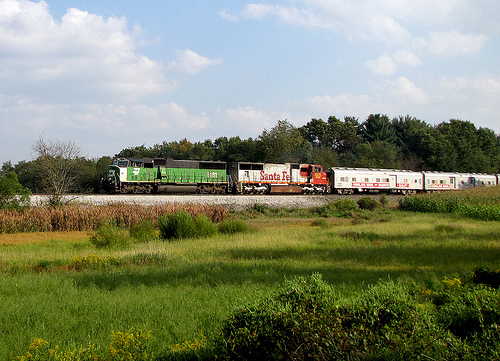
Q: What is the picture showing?
A: It is showing a field.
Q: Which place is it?
A: It is a field.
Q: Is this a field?
A: Yes, it is a field.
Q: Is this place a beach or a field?
A: It is a field.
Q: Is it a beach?
A: No, it is a field.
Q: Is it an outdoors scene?
A: Yes, it is outdoors.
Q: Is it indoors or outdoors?
A: It is outdoors.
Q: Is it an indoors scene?
A: No, it is outdoors.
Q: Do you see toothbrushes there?
A: No, there are no toothbrushes.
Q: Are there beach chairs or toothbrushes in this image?
A: No, there are no toothbrushes or beach chairs.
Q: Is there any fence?
A: No, there are no fences.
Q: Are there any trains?
A: Yes, there is a train.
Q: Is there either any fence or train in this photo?
A: Yes, there is a train.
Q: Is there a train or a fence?
A: Yes, there is a train.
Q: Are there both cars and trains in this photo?
A: Yes, there are both a train and a car.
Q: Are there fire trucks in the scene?
A: No, there are no fire trucks.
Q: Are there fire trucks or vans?
A: No, there are no fire trucks or vans.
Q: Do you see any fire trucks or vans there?
A: No, there are no fire trucks or vans.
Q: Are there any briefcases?
A: No, there are no briefcases.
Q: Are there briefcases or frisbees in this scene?
A: No, there are no briefcases or frisbees.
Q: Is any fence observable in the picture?
A: No, there are no fences.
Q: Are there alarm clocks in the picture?
A: No, there are no alarm clocks.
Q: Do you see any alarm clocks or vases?
A: No, there are no alarm clocks or vases.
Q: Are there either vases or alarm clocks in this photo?
A: No, there are no alarm clocks or vases.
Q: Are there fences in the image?
A: No, there are no fences.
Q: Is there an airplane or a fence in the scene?
A: No, there are no fences or airplanes.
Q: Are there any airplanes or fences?
A: No, there are no fences or airplanes.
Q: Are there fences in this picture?
A: No, there are no fences.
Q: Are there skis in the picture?
A: No, there are no skis.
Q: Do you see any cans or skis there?
A: No, there are no skis or cans.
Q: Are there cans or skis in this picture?
A: No, there are no skis or cans.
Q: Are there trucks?
A: Yes, there is a truck.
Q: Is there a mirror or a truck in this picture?
A: Yes, there is a truck.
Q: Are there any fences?
A: No, there are no fences.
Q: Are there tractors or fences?
A: No, there are no fences or tractors.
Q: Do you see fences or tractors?
A: No, there are no fences or tractors.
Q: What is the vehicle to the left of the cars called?
A: The vehicle is a truck.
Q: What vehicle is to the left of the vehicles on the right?
A: The vehicle is a truck.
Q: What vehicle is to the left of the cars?
A: The vehicle is a truck.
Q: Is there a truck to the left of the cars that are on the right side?
A: Yes, there is a truck to the left of the cars.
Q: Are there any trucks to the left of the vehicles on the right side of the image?
A: Yes, there is a truck to the left of the cars.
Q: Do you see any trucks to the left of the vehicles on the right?
A: Yes, there is a truck to the left of the cars.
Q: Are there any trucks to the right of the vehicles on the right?
A: No, the truck is to the left of the cars.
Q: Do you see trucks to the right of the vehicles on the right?
A: No, the truck is to the left of the cars.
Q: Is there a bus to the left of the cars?
A: No, there is a truck to the left of the cars.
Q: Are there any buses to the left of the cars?
A: No, there is a truck to the left of the cars.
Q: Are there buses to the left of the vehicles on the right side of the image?
A: No, there is a truck to the left of the cars.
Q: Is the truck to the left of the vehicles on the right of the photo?
A: Yes, the truck is to the left of the cars.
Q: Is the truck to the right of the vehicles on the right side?
A: No, the truck is to the left of the cars.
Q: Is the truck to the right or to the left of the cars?
A: The truck is to the left of the cars.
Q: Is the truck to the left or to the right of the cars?
A: The truck is to the left of the cars.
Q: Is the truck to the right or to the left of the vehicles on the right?
A: The truck is to the left of the cars.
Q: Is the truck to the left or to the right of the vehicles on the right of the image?
A: The truck is to the left of the cars.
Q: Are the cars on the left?
A: No, the cars are on the right of the image.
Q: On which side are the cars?
A: The cars are on the right of the image.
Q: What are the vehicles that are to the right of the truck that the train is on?
A: The vehicles are cars.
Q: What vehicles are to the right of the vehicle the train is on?
A: The vehicles are cars.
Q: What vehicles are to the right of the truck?
A: The vehicles are cars.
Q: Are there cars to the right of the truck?
A: Yes, there are cars to the right of the truck.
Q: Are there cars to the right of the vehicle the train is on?
A: Yes, there are cars to the right of the truck.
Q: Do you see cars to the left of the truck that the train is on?
A: No, the cars are to the right of the truck.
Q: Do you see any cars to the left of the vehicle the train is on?
A: No, the cars are to the right of the truck.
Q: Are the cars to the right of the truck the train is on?
A: Yes, the cars are to the right of the truck.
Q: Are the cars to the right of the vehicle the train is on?
A: Yes, the cars are to the right of the truck.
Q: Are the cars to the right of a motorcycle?
A: No, the cars are to the right of the truck.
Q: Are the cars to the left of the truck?
A: No, the cars are to the right of the truck.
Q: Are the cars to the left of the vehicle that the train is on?
A: No, the cars are to the right of the truck.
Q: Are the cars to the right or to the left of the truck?
A: The cars are to the right of the truck.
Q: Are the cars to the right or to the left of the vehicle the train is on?
A: The cars are to the right of the truck.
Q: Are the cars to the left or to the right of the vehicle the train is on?
A: The cars are to the right of the truck.